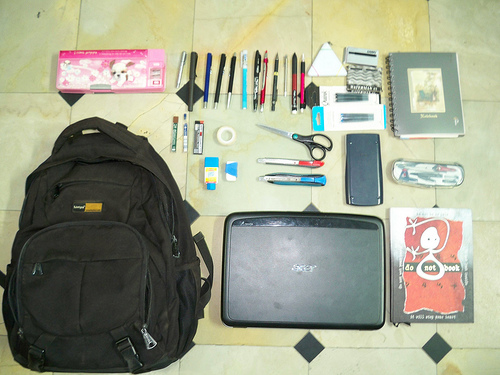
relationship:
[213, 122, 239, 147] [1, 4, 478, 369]
table on table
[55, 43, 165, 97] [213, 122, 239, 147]
geometry set on table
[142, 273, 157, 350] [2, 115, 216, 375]
zipper on a backpack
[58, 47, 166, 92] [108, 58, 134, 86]
box has a puppy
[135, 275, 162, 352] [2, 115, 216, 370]
zipper on backpack